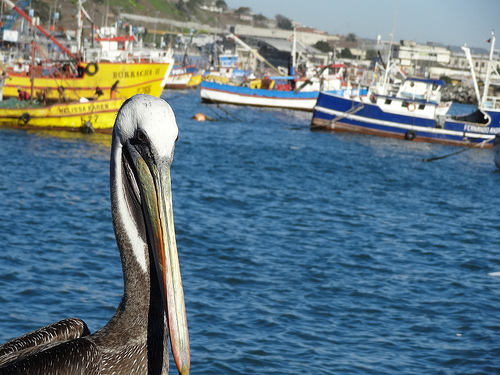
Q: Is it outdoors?
A: Yes, it is outdoors.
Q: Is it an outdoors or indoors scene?
A: It is outdoors.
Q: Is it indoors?
A: No, it is outdoors.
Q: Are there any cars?
A: No, there are no cars.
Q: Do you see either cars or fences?
A: No, there are no cars or fences.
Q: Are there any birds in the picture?
A: Yes, there is a bird.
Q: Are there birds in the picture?
A: Yes, there is a bird.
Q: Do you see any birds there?
A: Yes, there is a bird.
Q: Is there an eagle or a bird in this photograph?
A: Yes, there is a bird.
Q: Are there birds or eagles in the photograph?
A: Yes, there is a bird.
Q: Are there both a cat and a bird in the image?
A: No, there is a bird but no cats.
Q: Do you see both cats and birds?
A: No, there is a bird but no cats.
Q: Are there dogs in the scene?
A: No, there are no dogs.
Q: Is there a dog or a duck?
A: No, there are no dogs or ducks.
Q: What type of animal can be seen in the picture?
A: The animal is a bird.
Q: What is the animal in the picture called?
A: The animal is a bird.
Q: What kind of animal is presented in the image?
A: The animal is a bird.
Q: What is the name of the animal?
A: The animal is a bird.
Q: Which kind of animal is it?
A: The animal is a bird.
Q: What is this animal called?
A: This is a bird.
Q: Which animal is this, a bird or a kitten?
A: This is a bird.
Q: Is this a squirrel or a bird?
A: This is a bird.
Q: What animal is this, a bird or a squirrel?
A: This is a bird.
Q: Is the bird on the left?
A: Yes, the bird is on the left of the image.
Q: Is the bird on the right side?
A: No, the bird is on the left of the image.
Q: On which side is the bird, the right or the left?
A: The bird is on the left of the image.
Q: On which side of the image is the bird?
A: The bird is on the left of the image.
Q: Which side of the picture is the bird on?
A: The bird is on the left of the image.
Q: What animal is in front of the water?
A: The bird is in front of the water.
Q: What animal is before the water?
A: The bird is in front of the water.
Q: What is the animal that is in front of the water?
A: The animal is a bird.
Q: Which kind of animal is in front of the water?
A: The animal is a bird.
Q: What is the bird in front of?
A: The bird is in front of the water.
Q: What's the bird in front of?
A: The bird is in front of the water.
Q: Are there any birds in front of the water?
A: Yes, there is a bird in front of the water.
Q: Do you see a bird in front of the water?
A: Yes, there is a bird in front of the water.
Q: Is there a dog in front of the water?
A: No, there is a bird in front of the water.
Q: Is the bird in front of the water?
A: Yes, the bird is in front of the water.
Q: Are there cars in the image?
A: No, there are no cars.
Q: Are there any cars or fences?
A: No, there are no cars or fences.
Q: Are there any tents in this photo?
A: No, there are no tents.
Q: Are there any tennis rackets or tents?
A: No, there are no tents or tennis rackets.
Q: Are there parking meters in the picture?
A: No, there are no parking meters.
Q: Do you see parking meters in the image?
A: No, there are no parking meters.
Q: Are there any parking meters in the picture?
A: No, there are no parking meters.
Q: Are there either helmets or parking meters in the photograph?
A: No, there are no parking meters or helmets.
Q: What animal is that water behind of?
A: The water is behind the bird.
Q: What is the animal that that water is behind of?
A: The animal is a bird.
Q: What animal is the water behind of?
A: The water is behind the bird.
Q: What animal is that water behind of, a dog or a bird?
A: The water is behind a bird.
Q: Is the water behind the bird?
A: Yes, the water is behind the bird.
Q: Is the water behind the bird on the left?
A: Yes, the water is behind the bird.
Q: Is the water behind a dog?
A: No, the water is behind the bird.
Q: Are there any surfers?
A: No, there are no surfers.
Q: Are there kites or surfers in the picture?
A: No, there are no surfers or kites.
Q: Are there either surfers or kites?
A: No, there are no surfers or kites.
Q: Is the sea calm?
A: Yes, the sea is calm.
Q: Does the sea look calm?
A: Yes, the sea is calm.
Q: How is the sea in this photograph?
A: The sea is calm.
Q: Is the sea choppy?
A: No, the sea is calm.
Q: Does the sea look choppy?
A: No, the sea is calm.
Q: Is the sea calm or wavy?
A: The sea is calm.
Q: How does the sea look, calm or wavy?
A: The sea is calm.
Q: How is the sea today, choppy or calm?
A: The sea is calm.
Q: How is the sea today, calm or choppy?
A: The sea is calm.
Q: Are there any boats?
A: Yes, there is a boat.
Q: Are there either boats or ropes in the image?
A: Yes, there is a boat.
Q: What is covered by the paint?
A: The boat is covered by the paint.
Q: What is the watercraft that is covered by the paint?
A: The watercraft is a boat.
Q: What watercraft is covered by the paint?
A: The watercraft is a boat.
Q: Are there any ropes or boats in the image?
A: Yes, there is a boat.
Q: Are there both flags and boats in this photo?
A: No, there is a boat but no flags.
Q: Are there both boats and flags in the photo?
A: No, there is a boat but no flags.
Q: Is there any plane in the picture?
A: No, there are no airplanes.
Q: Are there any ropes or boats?
A: Yes, there is a boat.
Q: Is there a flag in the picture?
A: No, there are no flags.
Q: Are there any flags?
A: No, there are no flags.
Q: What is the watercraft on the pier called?
A: The watercraft is a boat.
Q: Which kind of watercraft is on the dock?
A: The watercraft is a boat.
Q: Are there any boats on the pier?
A: Yes, there is a boat on the pier.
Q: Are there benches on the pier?
A: No, there is a boat on the pier.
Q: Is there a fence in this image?
A: No, there are no fences.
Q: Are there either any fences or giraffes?
A: No, there are no fences or giraffes.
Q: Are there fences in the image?
A: No, there are no fences.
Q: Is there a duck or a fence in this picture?
A: No, there are no fences or ducks.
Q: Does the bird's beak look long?
A: Yes, the beak is long.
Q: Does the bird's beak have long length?
A: Yes, the beak is long.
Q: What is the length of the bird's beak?
A: The beak is long.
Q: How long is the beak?
A: The beak is long.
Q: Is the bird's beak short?
A: No, the beak is long.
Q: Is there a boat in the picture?
A: Yes, there is a boat.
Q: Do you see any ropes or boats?
A: Yes, there is a boat.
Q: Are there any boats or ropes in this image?
A: Yes, there is a boat.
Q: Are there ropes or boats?
A: Yes, there is a boat.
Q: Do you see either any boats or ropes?
A: Yes, there is a boat.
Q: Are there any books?
A: No, there are no books.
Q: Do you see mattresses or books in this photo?
A: No, there are no books or mattresses.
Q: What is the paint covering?
A: The paint is covering the boat.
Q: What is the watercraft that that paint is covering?
A: The watercraft is a boat.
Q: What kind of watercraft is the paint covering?
A: The paint is covering the boat.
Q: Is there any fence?
A: No, there are no fences.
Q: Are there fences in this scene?
A: No, there are no fences.